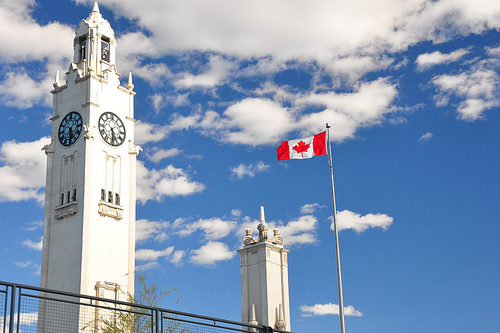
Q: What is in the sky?
A: Clouds.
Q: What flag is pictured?
A: Canadian.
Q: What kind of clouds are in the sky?
A: Wispy ones.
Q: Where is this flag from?
A: Canada.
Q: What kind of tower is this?
A: Clock tower.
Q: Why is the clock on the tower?
A: To show the time.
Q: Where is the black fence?
A: In front of the building.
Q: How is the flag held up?
A: By a metal pole.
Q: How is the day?
A: Sunny.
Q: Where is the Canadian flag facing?
A: To the left.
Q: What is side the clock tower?
A: Another tower.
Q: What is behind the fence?
A: A tree.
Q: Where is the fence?
A: In forefront.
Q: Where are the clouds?
A: In sky.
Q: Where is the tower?
A: In background.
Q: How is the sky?
A: Blue.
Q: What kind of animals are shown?
A: None.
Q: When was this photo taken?
A: Daytime.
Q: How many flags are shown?
A: One.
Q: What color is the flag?
A: Red & white.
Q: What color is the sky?
A: Blue.